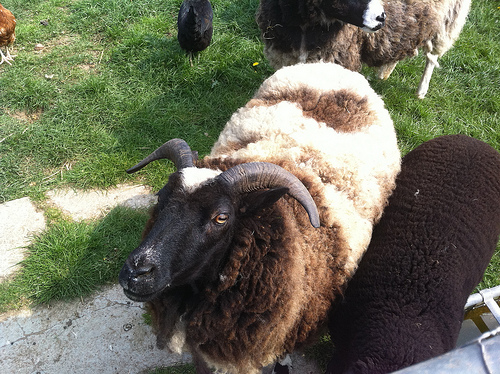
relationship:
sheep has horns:
[111, 47, 380, 351] [125, 136, 341, 227]